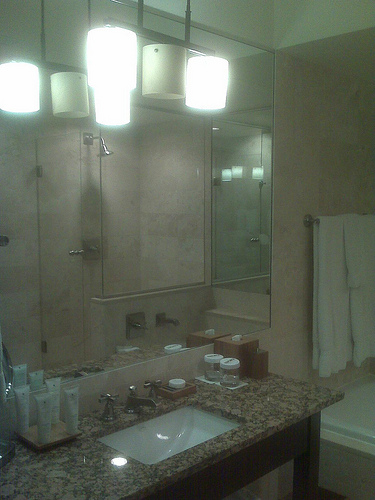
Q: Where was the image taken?
A: It was taken at the bathroom.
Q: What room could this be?
A: It is a bathroom.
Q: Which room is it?
A: It is a bathroom.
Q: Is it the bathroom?
A: Yes, it is the bathroom.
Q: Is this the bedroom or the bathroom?
A: It is the bathroom.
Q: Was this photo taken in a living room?
A: No, the picture was taken in a bathroom.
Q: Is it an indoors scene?
A: Yes, it is indoors.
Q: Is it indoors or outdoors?
A: It is indoors.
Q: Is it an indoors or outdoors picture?
A: It is indoors.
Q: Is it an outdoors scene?
A: No, it is indoors.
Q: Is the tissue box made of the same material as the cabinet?
A: Yes, both the tissue box and the cabinet are made of wood.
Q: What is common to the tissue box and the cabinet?
A: The material, both the tissue box and the cabinet are wooden.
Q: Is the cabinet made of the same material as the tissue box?
A: Yes, both the cabinet and the tissue box are made of wood.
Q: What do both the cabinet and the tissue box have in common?
A: The material, both the cabinet and the tissue box are wooden.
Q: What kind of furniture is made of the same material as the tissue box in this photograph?
A: The cabinet is made of the same material as the tissue box.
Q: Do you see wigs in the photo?
A: No, there are no wigs.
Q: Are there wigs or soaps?
A: No, there are no wigs or soaps.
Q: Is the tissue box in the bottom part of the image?
A: Yes, the tissue box is in the bottom of the image.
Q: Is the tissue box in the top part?
A: No, the tissue box is in the bottom of the image.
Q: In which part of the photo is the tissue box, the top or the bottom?
A: The tissue box is in the bottom of the image.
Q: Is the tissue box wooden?
A: Yes, the tissue box is wooden.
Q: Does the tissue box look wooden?
A: Yes, the tissue box is wooden.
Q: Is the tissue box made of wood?
A: Yes, the tissue box is made of wood.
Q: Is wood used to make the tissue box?
A: Yes, the tissue box is made of wood.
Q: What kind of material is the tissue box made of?
A: The tissue box is made of wood.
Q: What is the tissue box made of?
A: The tissue box is made of wood.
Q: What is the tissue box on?
A: The tissue box is on the counter.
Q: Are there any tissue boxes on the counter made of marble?
A: Yes, there is a tissue box on the counter.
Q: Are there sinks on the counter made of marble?
A: No, there is a tissue box on the counter.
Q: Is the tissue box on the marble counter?
A: Yes, the tissue box is on the counter.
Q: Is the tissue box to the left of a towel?
A: Yes, the tissue box is to the left of a towel.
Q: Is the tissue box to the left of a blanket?
A: No, the tissue box is to the left of a towel.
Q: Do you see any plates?
A: Yes, there is a plate.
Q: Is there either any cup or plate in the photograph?
A: Yes, there is a plate.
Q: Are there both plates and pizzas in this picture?
A: No, there is a plate but no pizzas.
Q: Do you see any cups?
A: No, there are no cups.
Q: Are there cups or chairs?
A: No, there are no cups or chairs.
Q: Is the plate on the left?
A: Yes, the plate is on the left of the image.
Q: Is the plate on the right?
A: No, the plate is on the left of the image.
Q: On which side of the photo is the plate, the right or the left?
A: The plate is on the left of the image.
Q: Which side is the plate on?
A: The plate is on the left of the image.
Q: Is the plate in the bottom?
A: Yes, the plate is in the bottom of the image.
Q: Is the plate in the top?
A: No, the plate is in the bottom of the image.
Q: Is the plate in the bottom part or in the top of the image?
A: The plate is in the bottom of the image.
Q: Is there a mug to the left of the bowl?
A: No, there is a plate to the left of the bowl.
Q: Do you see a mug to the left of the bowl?
A: No, there is a plate to the left of the bowl.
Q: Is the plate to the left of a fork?
A: No, the plate is to the left of the bowl.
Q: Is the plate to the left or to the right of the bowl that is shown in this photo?
A: The plate is to the left of the bowl.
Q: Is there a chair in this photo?
A: No, there are no chairs.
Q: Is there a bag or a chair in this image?
A: No, there are no chairs or bags.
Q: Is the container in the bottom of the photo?
A: Yes, the container is in the bottom of the image.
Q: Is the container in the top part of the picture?
A: No, the container is in the bottom of the image.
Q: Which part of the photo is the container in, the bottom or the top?
A: The container is in the bottom of the image.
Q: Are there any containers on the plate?
A: Yes, there is a container on the plate.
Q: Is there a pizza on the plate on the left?
A: No, there is a container on the plate.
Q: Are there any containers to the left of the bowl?
A: Yes, there is a container to the left of the bowl.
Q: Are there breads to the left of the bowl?
A: No, there is a container to the left of the bowl.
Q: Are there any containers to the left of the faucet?
A: Yes, there is a container to the left of the faucet.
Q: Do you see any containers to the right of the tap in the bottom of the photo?
A: No, the container is to the left of the tap.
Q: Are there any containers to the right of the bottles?
A: Yes, there is a container to the right of the bottles.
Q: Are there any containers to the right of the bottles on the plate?
A: Yes, there is a container to the right of the bottles.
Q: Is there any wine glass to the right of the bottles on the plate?
A: No, there is a container to the right of the bottles.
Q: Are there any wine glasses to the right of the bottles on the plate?
A: No, there is a container to the right of the bottles.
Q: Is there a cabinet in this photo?
A: Yes, there is a cabinet.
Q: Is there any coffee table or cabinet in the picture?
A: Yes, there is a cabinet.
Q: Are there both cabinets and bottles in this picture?
A: Yes, there are both a cabinet and a bottle.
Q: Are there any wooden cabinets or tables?
A: Yes, there is a wood cabinet.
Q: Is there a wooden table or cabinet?
A: Yes, there is a wood cabinet.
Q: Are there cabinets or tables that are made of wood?
A: Yes, the cabinet is made of wood.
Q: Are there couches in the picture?
A: No, there are no couches.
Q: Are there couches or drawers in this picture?
A: No, there are no couches or drawers.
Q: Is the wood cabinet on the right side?
A: Yes, the cabinet is on the right of the image.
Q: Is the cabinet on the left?
A: No, the cabinet is on the right of the image.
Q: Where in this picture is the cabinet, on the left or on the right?
A: The cabinet is on the right of the image.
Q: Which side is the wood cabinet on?
A: The cabinet is on the right of the image.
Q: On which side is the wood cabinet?
A: The cabinet is on the right of the image.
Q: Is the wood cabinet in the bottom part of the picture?
A: Yes, the cabinet is in the bottom of the image.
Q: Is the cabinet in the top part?
A: No, the cabinet is in the bottom of the image.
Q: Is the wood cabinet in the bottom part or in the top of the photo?
A: The cabinet is in the bottom of the image.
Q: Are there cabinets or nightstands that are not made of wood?
A: No, there is a cabinet but it is made of wood.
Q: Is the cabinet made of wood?
A: Yes, the cabinet is made of wood.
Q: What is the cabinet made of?
A: The cabinet is made of wood.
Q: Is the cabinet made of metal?
A: No, the cabinet is made of wood.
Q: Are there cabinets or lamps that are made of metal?
A: No, there is a cabinet but it is made of wood.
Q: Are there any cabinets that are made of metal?
A: No, there is a cabinet but it is made of wood.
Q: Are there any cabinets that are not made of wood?
A: No, there is a cabinet but it is made of wood.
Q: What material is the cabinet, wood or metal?
A: The cabinet is made of wood.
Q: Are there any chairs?
A: No, there are no chairs.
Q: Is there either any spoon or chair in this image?
A: No, there are no chairs or spoons.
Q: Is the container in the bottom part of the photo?
A: Yes, the container is in the bottom of the image.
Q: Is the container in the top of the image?
A: No, the container is in the bottom of the image.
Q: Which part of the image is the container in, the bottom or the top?
A: The container is in the bottom of the image.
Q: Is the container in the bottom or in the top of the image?
A: The container is in the bottom of the image.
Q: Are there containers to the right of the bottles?
A: Yes, there is a container to the right of the bottles.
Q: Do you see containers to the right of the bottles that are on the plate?
A: Yes, there is a container to the right of the bottles.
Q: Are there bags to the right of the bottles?
A: No, there is a container to the right of the bottles.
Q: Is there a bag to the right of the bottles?
A: No, there is a container to the right of the bottles.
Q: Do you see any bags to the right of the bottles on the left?
A: No, there is a container to the right of the bottles.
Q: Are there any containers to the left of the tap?
A: Yes, there is a container to the left of the tap.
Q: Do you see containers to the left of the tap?
A: Yes, there is a container to the left of the tap.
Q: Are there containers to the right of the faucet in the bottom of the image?
A: No, the container is to the left of the faucet.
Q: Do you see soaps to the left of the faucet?
A: No, there is a container to the left of the faucet.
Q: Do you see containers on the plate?
A: Yes, there is a container on the plate.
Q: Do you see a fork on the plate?
A: No, there is a container on the plate.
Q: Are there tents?
A: No, there are no tents.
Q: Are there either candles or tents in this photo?
A: No, there are no tents or candles.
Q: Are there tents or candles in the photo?
A: No, there are no tents or candles.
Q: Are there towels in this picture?
A: Yes, there is a towel.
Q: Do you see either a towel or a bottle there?
A: Yes, there is a towel.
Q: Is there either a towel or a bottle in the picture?
A: Yes, there is a towel.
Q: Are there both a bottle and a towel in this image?
A: Yes, there are both a towel and a bottle.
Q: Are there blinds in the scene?
A: No, there are no blinds.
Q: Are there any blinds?
A: No, there are no blinds.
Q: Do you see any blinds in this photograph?
A: No, there are no blinds.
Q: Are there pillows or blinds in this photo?
A: No, there are no blinds or pillows.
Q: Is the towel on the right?
A: Yes, the towel is on the right of the image.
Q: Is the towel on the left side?
A: No, the towel is on the right of the image.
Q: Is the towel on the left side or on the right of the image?
A: The towel is on the right of the image.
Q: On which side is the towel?
A: The towel is on the right of the image.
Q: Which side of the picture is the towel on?
A: The towel is on the right of the image.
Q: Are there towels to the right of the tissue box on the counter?
A: Yes, there is a towel to the right of the tissue box.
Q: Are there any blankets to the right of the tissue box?
A: No, there is a towel to the right of the tissue box.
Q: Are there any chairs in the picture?
A: No, there are no chairs.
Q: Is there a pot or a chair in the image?
A: No, there are no chairs or pots.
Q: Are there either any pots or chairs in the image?
A: No, there are no chairs or pots.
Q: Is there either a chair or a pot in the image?
A: No, there are no chairs or pots.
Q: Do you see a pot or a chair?
A: No, there are no chairs or pots.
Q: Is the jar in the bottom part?
A: Yes, the jar is in the bottom of the image.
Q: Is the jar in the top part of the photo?
A: No, the jar is in the bottom of the image.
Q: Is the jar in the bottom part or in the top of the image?
A: The jar is in the bottom of the image.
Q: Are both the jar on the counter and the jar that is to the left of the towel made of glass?
A: Yes, both the jar and the jar are made of glass.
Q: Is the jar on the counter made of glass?
A: Yes, the jar is made of glass.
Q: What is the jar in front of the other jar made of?
A: The jar is made of glass.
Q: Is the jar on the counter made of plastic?
A: No, the jar is made of glass.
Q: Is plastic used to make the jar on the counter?
A: No, the jar is made of glass.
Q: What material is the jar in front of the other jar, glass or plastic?
A: The jar is made of glass.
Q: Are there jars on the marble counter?
A: Yes, there is a jar on the counter.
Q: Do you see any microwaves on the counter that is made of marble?
A: No, there is a jar on the counter.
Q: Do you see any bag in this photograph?
A: No, there are no bags.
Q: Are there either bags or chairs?
A: No, there are no bags or chairs.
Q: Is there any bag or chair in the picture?
A: No, there are no bags or chairs.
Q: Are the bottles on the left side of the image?
A: Yes, the bottles are on the left of the image.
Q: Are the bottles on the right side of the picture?
A: No, the bottles are on the left of the image.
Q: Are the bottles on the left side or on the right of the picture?
A: The bottles are on the left of the image.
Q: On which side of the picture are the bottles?
A: The bottles are on the left of the image.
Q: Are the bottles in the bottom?
A: Yes, the bottles are in the bottom of the image.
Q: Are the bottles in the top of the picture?
A: No, the bottles are in the bottom of the image.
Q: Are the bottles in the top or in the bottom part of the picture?
A: The bottles are in the bottom of the image.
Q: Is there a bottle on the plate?
A: Yes, there are bottles on the plate.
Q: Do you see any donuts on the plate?
A: No, there are bottles on the plate.